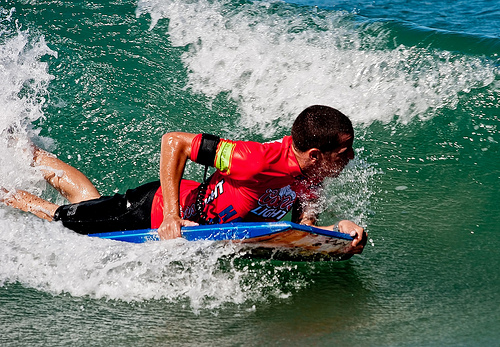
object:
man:
[0, 103, 367, 255]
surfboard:
[90, 223, 360, 258]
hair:
[290, 104, 353, 152]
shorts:
[53, 178, 161, 235]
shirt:
[148, 135, 323, 230]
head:
[288, 105, 353, 177]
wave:
[170, 12, 489, 121]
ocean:
[0, 0, 499, 346]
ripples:
[381, 217, 491, 276]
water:
[5, 3, 128, 102]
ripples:
[28, 305, 181, 343]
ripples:
[97, 41, 165, 103]